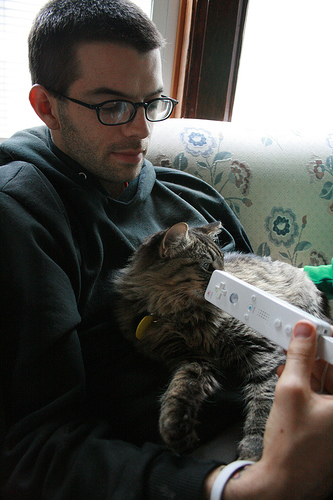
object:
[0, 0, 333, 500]
man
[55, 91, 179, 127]
eyeglass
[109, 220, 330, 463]
cat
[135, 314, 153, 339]
pendant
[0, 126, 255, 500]
jacket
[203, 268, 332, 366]
controller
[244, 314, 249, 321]
buttons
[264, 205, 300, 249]
flowers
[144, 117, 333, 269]
sofa